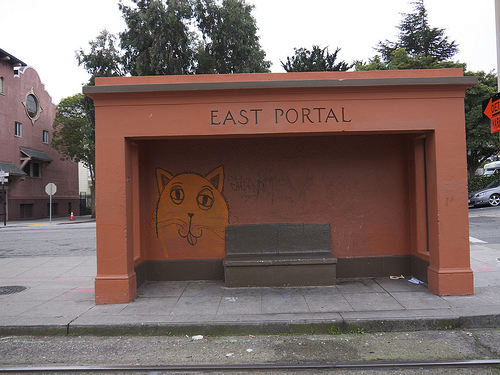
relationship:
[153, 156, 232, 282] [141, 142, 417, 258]
cat on wall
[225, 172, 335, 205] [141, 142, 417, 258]
graffiti on wall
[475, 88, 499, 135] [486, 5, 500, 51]
sign on post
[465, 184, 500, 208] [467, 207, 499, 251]
car on street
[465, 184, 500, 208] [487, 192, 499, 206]
car has tire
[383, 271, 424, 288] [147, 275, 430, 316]
paper on ground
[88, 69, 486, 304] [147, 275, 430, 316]
bus stop on ground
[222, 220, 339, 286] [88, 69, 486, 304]
bench in bus stop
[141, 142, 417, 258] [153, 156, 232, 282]
wall has cat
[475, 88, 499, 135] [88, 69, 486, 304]
sign by bus stop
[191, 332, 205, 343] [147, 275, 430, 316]
garbage on ground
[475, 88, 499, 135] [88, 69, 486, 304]
sign near bus stop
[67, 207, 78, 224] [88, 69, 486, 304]
cone by bus stop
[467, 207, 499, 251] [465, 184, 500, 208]
street has car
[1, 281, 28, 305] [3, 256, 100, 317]
drain on pavement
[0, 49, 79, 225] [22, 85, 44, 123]
building has window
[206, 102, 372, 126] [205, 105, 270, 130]
letters spell east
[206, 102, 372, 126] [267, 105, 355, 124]
letters spell portal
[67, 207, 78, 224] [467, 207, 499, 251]
cone on street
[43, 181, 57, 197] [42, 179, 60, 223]
back of sign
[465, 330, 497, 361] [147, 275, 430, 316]
hole on ground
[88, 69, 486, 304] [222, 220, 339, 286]
bus stop around bench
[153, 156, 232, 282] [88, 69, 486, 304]
cat drawn on bus stop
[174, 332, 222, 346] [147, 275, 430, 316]
garbage on ground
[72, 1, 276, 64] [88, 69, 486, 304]
tree around bus stop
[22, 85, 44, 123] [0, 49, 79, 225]
window on building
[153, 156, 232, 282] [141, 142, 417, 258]
painting on wall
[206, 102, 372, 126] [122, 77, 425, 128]
letters on wall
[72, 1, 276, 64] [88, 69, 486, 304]
tree behind bus stop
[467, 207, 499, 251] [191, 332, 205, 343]
street has garbage